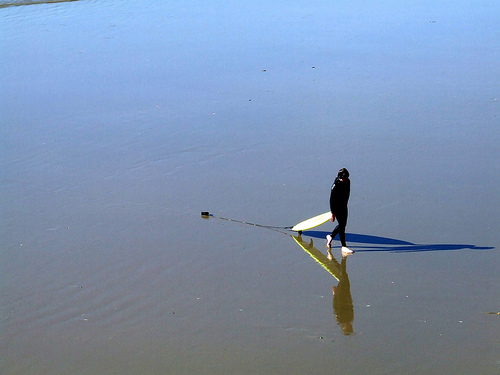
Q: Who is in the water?
A: The surfer.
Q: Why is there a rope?
A: To attach board to ankle.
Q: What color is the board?
A: White.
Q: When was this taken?
A: Daytime.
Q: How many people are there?
A: One.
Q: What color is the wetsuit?
A: Black.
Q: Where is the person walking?
A: In the shallow water.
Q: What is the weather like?
A: Sunny.